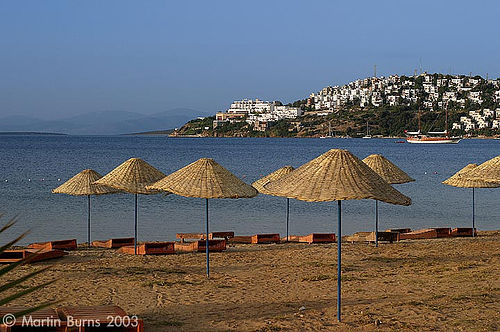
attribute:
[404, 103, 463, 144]
boat — floating, sailing, white, large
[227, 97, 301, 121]
building — white, large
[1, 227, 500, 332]
beach — sand, clear, flat, calm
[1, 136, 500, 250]
water — calm, flat, blue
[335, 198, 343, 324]
pole — blue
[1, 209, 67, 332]
leaves — green, palm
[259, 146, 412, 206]
umbrella — straw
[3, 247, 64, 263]
chair — empty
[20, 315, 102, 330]
letters — white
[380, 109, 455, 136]
bushes — green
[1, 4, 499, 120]
sky — blue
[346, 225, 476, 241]
chairs — empty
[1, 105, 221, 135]
mountains — hazy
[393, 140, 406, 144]
people — swimming